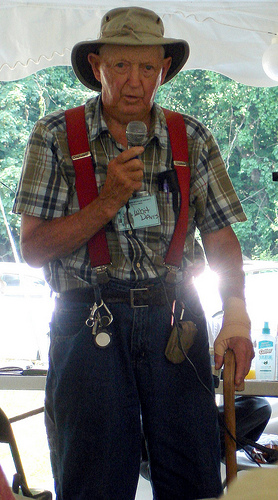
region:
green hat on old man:
[65, 5, 195, 100]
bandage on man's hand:
[207, 295, 257, 362]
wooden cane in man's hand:
[218, 340, 255, 476]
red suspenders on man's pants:
[58, 94, 208, 300]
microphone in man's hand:
[119, 112, 153, 167]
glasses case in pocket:
[152, 162, 188, 217]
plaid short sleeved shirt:
[15, 103, 244, 288]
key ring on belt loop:
[85, 295, 125, 353]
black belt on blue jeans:
[45, 272, 205, 311]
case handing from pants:
[158, 318, 198, 372]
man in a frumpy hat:
[67, 5, 194, 115]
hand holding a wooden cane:
[211, 339, 251, 492]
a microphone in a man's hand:
[110, 113, 154, 226]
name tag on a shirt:
[110, 191, 162, 235]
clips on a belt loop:
[79, 289, 115, 355]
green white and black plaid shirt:
[9, 102, 241, 296]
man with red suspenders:
[60, 100, 199, 302]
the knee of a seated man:
[226, 391, 275, 450]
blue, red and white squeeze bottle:
[253, 318, 277, 383]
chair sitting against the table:
[0, 397, 53, 497]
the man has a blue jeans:
[88, 391, 196, 477]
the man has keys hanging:
[78, 317, 116, 347]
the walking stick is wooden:
[221, 392, 246, 483]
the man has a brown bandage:
[218, 299, 276, 346]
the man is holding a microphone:
[63, 112, 273, 297]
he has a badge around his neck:
[114, 161, 225, 222]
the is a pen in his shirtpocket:
[158, 169, 181, 219]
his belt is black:
[78, 282, 223, 310]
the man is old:
[65, 59, 249, 251]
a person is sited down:
[225, 386, 275, 434]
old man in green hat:
[58, 7, 215, 128]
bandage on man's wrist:
[210, 292, 268, 357]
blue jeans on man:
[49, 277, 218, 487]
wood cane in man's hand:
[211, 347, 254, 472]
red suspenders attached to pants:
[61, 103, 200, 292]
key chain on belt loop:
[84, 297, 114, 350]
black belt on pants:
[64, 277, 189, 307]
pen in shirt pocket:
[161, 178, 177, 204]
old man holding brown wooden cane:
[10, 1, 260, 498]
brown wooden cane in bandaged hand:
[208, 292, 269, 496]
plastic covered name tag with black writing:
[112, 194, 163, 229]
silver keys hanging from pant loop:
[82, 280, 119, 357]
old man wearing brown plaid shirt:
[14, 4, 257, 493]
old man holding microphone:
[7, 1, 266, 492]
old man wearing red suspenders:
[8, 2, 255, 495]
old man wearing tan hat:
[6, 3, 256, 496]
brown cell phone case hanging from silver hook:
[162, 291, 205, 371]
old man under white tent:
[3, 0, 273, 495]